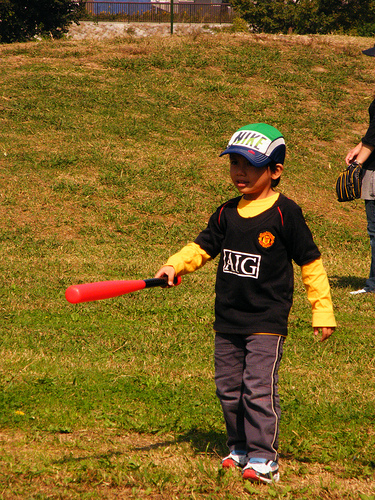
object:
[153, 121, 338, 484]
boy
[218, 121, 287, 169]
hat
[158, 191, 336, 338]
shirt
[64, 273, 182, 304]
bat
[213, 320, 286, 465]
pants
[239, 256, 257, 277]
letters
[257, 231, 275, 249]
label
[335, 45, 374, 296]
person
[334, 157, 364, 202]
mit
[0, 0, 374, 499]
baseball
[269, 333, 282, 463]
line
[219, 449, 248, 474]
shoes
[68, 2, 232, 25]
fence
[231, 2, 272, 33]
trees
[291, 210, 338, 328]
long sleeves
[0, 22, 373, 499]
lawn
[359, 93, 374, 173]
jacket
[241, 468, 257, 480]
tip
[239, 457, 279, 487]
shoe